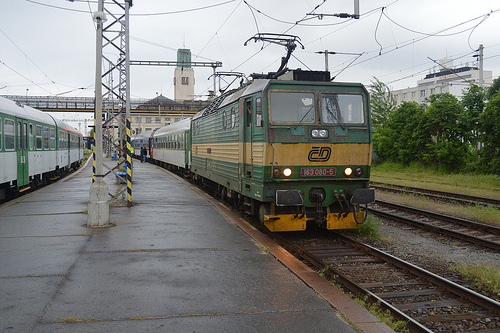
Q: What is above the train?
A: Wires.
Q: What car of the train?
A: Front.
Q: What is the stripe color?
A: Yellow.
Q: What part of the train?
A: Front.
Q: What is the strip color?
A: Yellow.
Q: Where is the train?
A: Station.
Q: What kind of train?
A: Passengers.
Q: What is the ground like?
A: Wet.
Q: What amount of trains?
A: Two.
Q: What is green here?
A: Trees.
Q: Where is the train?
A: On the tracks.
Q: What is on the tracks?
A: Trains.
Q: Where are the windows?
A: On the train.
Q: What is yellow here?
A: Train.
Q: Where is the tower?
A: Behind the train.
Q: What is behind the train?
A: A tower.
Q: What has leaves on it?
A: The trees.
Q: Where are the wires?
A: Over the train.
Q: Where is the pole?
A: Left of train.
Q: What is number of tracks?
A: Three.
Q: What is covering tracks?
A: Grass.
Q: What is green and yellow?
A: Front of train.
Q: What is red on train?
A: License plate.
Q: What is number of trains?
A: Two.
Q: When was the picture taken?
A: Daytime.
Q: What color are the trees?
A: Green.